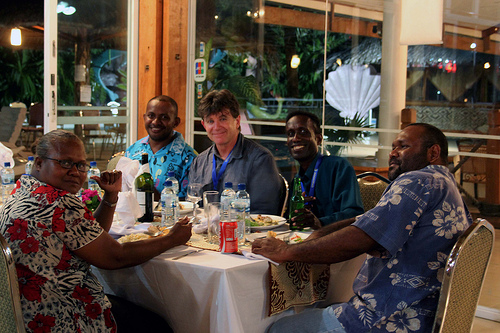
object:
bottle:
[289, 178, 305, 232]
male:
[188, 89, 282, 216]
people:
[0, 89, 475, 333]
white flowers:
[432, 201, 470, 240]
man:
[251, 122, 474, 331]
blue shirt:
[330, 165, 472, 333]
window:
[405, 44, 500, 107]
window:
[43, 0, 137, 159]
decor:
[322, 62, 379, 125]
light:
[290, 55, 300, 69]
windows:
[193, 0, 381, 155]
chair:
[430, 217, 496, 333]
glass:
[208, 202, 224, 245]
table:
[88, 189, 366, 333]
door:
[0, 0, 133, 139]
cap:
[225, 182, 233, 188]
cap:
[238, 183, 246, 190]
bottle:
[236, 182, 251, 234]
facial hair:
[388, 151, 431, 181]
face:
[388, 125, 427, 181]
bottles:
[220, 182, 236, 202]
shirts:
[291, 152, 365, 227]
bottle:
[135, 153, 154, 223]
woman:
[0, 129, 192, 333]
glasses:
[41, 156, 92, 172]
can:
[219, 219, 238, 253]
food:
[250, 214, 278, 226]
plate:
[248, 214, 287, 230]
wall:
[1, 0, 497, 131]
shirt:
[185, 133, 280, 215]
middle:
[130, 193, 232, 240]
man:
[285, 111, 365, 230]